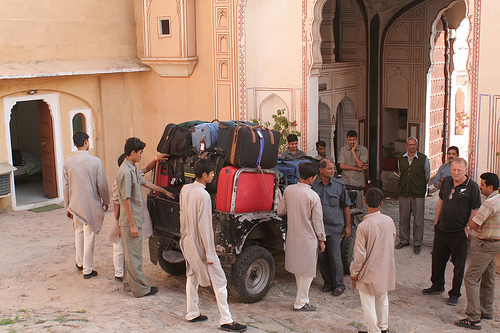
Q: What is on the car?
A: Luggage.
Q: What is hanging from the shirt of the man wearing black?
A: Glasses.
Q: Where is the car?
A: In the middle.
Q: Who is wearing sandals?
A: The man on the right.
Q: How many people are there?
A: 14.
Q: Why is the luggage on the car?
A: They are taking it somewhere.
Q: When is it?
A: Day time.